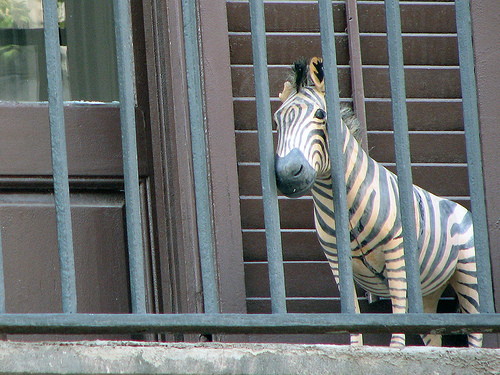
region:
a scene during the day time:
[2, 0, 499, 374]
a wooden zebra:
[252, 39, 497, 361]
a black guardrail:
[2, 4, 499, 354]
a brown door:
[2, 0, 248, 352]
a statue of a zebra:
[253, 66, 485, 293]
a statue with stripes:
[244, 81, 494, 361]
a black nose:
[248, 116, 328, 229]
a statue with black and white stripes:
[203, 35, 493, 293]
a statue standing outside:
[214, 47, 444, 355]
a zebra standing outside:
[242, 55, 458, 277]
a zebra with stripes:
[272, 90, 482, 369]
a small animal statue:
[212, 45, 476, 365]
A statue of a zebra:
[273, 59, 484, 344]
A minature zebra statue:
[274, 55, 486, 347]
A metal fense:
[0, 1, 499, 331]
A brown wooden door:
[0, 0, 160, 340]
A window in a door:
[0, 0, 136, 105]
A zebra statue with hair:
[291, 57, 302, 87]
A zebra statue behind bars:
[0, 0, 498, 330]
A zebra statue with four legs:
[273, 58, 484, 345]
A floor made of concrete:
[1, 339, 498, 374]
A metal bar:
[112, 0, 147, 315]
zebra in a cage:
[252, 68, 498, 365]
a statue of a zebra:
[248, 55, 483, 297]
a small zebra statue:
[250, 20, 482, 325]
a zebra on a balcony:
[228, 47, 498, 325]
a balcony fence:
[18, 13, 497, 372]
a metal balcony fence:
[12, 26, 471, 373]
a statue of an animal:
[261, 48, 494, 335]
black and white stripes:
[257, 75, 492, 343]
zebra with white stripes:
[291, 101, 492, 300]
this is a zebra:
[26, 14, 452, 281]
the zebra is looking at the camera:
[253, 49, 375, 203]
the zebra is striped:
[277, 87, 444, 327]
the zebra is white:
[293, 106, 425, 265]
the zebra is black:
[275, 109, 471, 289]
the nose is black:
[275, 159, 305, 193]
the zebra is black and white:
[293, 153, 415, 262]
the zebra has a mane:
[282, 68, 334, 110]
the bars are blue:
[134, 36, 435, 211]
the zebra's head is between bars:
[266, 49, 422, 241]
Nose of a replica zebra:
[281, 138, 318, 198]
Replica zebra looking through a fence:
[238, 31, 475, 318]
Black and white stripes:
[354, 158, 441, 263]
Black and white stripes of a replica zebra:
[354, 149, 450, 264]